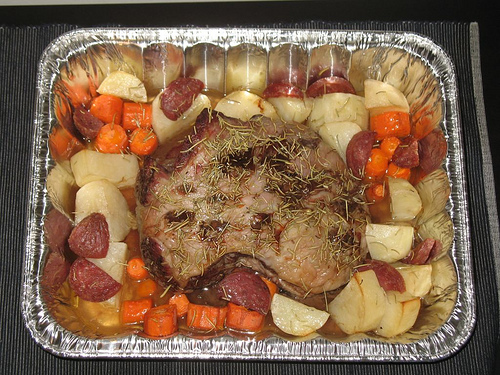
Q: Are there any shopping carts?
A: No, there are no shopping carts.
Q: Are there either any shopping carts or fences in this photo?
A: No, there are no shopping carts or fences.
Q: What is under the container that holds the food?
A: The mat is under the container.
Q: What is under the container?
A: The mat is under the container.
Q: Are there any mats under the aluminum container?
A: Yes, there is a mat under the container.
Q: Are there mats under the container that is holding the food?
A: Yes, there is a mat under the container.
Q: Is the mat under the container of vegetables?
A: Yes, the mat is under the container.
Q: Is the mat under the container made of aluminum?
A: Yes, the mat is under the container.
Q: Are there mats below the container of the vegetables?
A: Yes, there is a mat below the container.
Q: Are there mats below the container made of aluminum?
A: Yes, there is a mat below the container.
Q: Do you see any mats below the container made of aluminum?
A: Yes, there is a mat below the container.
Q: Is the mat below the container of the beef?
A: Yes, the mat is below the container.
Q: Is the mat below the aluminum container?
A: Yes, the mat is below the container.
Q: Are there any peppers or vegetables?
A: Yes, there are vegetables.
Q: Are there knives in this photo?
A: No, there are no knives.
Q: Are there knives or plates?
A: No, there are no knives or plates.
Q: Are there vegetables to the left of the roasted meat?
A: Yes, there are vegetables to the left of the beef.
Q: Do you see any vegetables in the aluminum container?
A: Yes, there are vegetables in the container.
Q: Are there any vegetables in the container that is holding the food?
A: Yes, there are vegetables in the container.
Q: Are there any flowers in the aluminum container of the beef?
A: No, there are vegetables in the container.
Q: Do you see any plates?
A: No, there are no plates.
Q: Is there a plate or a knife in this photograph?
A: No, there are no plates or knives.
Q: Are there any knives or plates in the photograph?
A: No, there are no plates or knives.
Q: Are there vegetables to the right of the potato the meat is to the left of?
A: Yes, there are vegetables to the right of the potato.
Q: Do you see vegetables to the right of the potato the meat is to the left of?
A: Yes, there are vegetables to the right of the potato.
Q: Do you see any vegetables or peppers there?
A: Yes, there are vegetables.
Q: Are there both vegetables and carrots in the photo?
A: Yes, there are both vegetables and a carrot.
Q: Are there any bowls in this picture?
A: No, there are no bowls.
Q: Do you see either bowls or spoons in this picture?
A: No, there are no bowls or spoons.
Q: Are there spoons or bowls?
A: No, there are no bowls or spoons.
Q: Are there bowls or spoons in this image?
A: No, there are no bowls or spoons.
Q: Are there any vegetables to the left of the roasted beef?
A: Yes, there are vegetables to the left of the beef.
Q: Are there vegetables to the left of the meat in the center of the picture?
A: Yes, there are vegetables to the left of the beef.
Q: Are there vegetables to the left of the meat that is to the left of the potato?
A: Yes, there are vegetables to the left of the meat.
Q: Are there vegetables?
A: Yes, there are vegetables.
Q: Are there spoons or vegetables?
A: Yes, there are vegetables.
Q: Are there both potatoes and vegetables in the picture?
A: Yes, there are both vegetables and potatoes.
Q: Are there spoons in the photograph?
A: No, there are no spoons.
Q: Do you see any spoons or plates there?
A: No, there are no spoons or plates.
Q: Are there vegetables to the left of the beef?
A: Yes, there are vegetables to the left of the beef.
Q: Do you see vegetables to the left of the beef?
A: Yes, there are vegetables to the left of the beef.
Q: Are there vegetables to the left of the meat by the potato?
A: Yes, there are vegetables to the left of the beef.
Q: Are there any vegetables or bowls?
A: Yes, there are vegetables.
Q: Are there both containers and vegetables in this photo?
A: Yes, there are both vegetables and a container.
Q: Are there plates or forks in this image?
A: No, there are no plates or forks.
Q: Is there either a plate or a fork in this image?
A: No, there are no plates or forks.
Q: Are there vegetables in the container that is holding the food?
A: Yes, there are vegetables in the container.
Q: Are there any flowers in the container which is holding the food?
A: No, there are vegetables in the container.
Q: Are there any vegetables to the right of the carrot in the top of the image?
A: Yes, there are vegetables to the right of the carrot.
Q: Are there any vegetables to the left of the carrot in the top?
A: No, the vegetables are to the right of the carrot.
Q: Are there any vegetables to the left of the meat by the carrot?
A: Yes, there are vegetables to the left of the meat.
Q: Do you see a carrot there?
A: Yes, there is a carrot.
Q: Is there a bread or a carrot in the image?
A: Yes, there is a carrot.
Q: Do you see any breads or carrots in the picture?
A: Yes, there is a carrot.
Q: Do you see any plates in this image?
A: No, there are no plates.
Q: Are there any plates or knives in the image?
A: No, there are no plates or knives.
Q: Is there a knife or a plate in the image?
A: No, there are no plates or knives.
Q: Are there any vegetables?
A: Yes, there are vegetables.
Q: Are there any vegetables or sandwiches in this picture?
A: Yes, there are vegetables.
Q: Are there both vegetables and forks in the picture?
A: No, there are vegetables but no forks.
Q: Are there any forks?
A: No, there are no forks.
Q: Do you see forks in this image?
A: No, there are no forks.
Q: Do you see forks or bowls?
A: No, there are no forks or bowls.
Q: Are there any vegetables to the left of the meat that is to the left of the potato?
A: Yes, there are vegetables to the left of the meat.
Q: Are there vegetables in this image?
A: Yes, there are vegetables.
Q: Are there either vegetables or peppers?
A: Yes, there are vegetables.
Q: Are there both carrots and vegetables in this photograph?
A: Yes, there are both vegetables and a carrot.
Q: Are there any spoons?
A: No, there are no spoons.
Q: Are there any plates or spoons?
A: No, there are no spoons or plates.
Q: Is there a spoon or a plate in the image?
A: No, there are no spoons or plates.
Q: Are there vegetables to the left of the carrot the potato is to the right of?
A: Yes, there are vegetables to the left of the carrot.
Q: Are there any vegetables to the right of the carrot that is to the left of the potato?
A: No, the vegetables are to the left of the carrot.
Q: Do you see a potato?
A: Yes, there is a potato.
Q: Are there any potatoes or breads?
A: Yes, there is a potato.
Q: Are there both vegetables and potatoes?
A: Yes, there are both a potato and vegetables.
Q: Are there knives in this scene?
A: No, there are no knives.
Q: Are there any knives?
A: No, there are no knives.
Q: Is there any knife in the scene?
A: No, there are no knives.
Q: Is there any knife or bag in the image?
A: No, there are no knives or bags.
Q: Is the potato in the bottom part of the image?
A: Yes, the potato is in the bottom of the image.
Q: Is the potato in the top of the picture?
A: No, the potato is in the bottom of the image.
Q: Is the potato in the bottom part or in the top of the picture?
A: The potato is in the bottom of the image.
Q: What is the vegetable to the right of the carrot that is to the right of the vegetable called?
A: The vegetable is a potato.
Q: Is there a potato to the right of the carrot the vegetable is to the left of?
A: Yes, there is a potato to the right of the carrot.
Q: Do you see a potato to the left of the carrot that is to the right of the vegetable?
A: No, the potato is to the right of the carrot.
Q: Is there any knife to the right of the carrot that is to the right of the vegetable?
A: No, there is a potato to the right of the carrot.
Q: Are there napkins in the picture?
A: No, there are no napkins.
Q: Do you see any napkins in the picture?
A: No, there are no napkins.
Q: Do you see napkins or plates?
A: No, there are no napkins or plates.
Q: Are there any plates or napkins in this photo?
A: No, there are no napkins or plates.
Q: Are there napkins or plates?
A: No, there are no napkins or plates.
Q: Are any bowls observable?
A: No, there are no bowls.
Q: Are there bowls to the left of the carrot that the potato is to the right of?
A: No, there is a vegetable to the left of the carrot.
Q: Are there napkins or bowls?
A: No, there are no bowls or napkins.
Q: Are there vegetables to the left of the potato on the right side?
A: Yes, there is a vegetable to the left of the potato.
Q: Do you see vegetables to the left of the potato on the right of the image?
A: Yes, there is a vegetable to the left of the potato.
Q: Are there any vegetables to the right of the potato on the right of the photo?
A: No, the vegetable is to the left of the potato.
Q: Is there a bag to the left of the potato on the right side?
A: No, there is a vegetable to the left of the potato.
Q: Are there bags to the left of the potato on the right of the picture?
A: No, there is a vegetable to the left of the potato.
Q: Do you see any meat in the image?
A: Yes, there is meat.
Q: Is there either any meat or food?
A: Yes, there is meat.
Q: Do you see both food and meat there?
A: Yes, there are both meat and food.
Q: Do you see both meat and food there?
A: Yes, there are both meat and food.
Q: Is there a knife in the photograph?
A: No, there are no knives.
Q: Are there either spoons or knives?
A: No, there are no knives or spoons.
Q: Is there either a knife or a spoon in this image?
A: No, there are no knives or spoons.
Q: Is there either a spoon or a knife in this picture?
A: No, there are no knives or spoons.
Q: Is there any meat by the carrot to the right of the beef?
A: Yes, there is meat by the carrot.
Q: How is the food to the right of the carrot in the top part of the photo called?
A: The food is meat.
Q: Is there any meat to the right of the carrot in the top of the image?
A: Yes, there is meat to the right of the carrot.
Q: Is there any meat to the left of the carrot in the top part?
A: No, the meat is to the right of the carrot.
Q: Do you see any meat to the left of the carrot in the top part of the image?
A: No, the meat is to the right of the carrot.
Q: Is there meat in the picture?
A: Yes, there is meat.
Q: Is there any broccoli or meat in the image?
A: Yes, there is meat.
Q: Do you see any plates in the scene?
A: No, there are no plates.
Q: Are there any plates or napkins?
A: No, there are no plates or napkins.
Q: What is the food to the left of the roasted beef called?
A: The food is meat.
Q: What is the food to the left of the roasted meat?
A: The food is meat.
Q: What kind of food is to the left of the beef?
A: The food is meat.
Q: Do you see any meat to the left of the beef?
A: Yes, there is meat to the left of the beef.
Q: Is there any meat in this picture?
A: Yes, there is meat.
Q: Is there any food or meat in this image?
A: Yes, there is meat.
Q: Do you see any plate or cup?
A: No, there are no plates or cups.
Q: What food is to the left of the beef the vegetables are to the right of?
A: The food is meat.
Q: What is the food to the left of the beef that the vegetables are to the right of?
A: The food is meat.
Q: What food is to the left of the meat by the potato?
A: The food is meat.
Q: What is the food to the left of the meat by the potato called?
A: The food is meat.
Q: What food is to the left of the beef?
A: The food is meat.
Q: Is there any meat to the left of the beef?
A: Yes, there is meat to the left of the beef.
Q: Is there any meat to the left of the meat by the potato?
A: Yes, there is meat to the left of the beef.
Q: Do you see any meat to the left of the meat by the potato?
A: Yes, there is meat to the left of the beef.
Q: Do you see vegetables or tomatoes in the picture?
A: Yes, there are vegetables.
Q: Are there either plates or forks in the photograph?
A: No, there are no plates or forks.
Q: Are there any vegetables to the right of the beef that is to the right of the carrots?
A: Yes, there are vegetables to the right of the beef.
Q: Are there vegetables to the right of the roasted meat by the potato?
A: Yes, there are vegetables to the right of the beef.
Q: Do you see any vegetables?
A: Yes, there are vegetables.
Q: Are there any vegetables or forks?
A: Yes, there are vegetables.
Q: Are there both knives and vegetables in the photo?
A: No, there are vegetables but no knives.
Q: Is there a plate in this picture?
A: No, there are no plates.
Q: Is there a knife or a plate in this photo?
A: No, there are no plates or knives.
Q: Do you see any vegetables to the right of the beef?
A: Yes, there are vegetables to the right of the beef.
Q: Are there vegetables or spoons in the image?
A: Yes, there are vegetables.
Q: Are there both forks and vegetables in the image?
A: No, there are vegetables but no forks.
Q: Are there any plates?
A: No, there are no plates.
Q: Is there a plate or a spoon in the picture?
A: No, there are no plates or spoons.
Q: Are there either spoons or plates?
A: No, there are no plates or spoons.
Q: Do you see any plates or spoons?
A: No, there are no plates or spoons.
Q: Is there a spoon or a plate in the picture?
A: No, there are no plates or spoons.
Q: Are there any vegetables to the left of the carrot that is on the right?
A: Yes, there are vegetables to the left of the carrot.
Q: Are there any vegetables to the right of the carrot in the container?
A: No, the vegetables are to the left of the carrot.